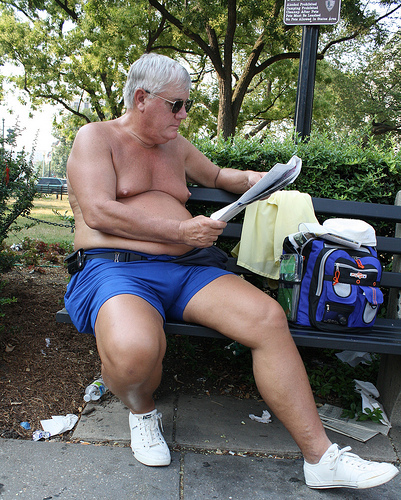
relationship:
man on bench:
[68, 49, 303, 474] [89, 182, 400, 346]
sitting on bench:
[64, 219, 231, 342] [89, 182, 400, 346]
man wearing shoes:
[68, 49, 303, 474] [126, 412, 173, 468]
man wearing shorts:
[68, 49, 303, 474] [67, 246, 233, 324]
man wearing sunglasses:
[68, 49, 303, 474] [164, 93, 194, 118]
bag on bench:
[280, 232, 383, 334] [89, 182, 400, 346]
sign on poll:
[282, 0, 342, 27] [298, 25, 316, 146]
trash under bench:
[321, 380, 389, 441] [89, 182, 400, 346]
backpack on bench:
[280, 232, 383, 334] [89, 182, 400, 346]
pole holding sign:
[298, 25, 316, 146] [282, 0, 342, 27]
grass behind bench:
[26, 197, 71, 227] [89, 182, 400, 346]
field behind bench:
[36, 185, 71, 222] [89, 182, 400, 346]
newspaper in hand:
[213, 153, 303, 224] [191, 214, 229, 247]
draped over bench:
[261, 188, 319, 272] [89, 182, 400, 346]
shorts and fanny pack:
[67, 246, 233, 324] [124, 247, 233, 267]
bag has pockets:
[280, 232, 383, 334] [326, 282, 381, 327]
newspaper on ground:
[323, 403, 393, 443] [319, 397, 401, 461]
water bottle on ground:
[81, 380, 106, 403] [81, 387, 117, 424]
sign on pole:
[282, 0, 342, 27] [298, 25, 316, 146]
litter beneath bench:
[321, 380, 389, 441] [89, 182, 400, 346]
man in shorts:
[68, 49, 303, 474] [67, 246, 233, 324]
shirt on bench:
[271, 188, 318, 237] [89, 182, 400, 346]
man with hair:
[68, 49, 303, 474] [126, 52, 190, 99]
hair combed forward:
[126, 52, 190, 99] [157, 58, 190, 85]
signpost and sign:
[298, 25, 316, 146] [282, 0, 342, 27]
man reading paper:
[68, 49, 303, 474] [213, 153, 303, 224]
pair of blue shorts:
[67, 246, 233, 324] [64, 219, 231, 342]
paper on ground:
[321, 380, 389, 441] [319, 397, 401, 461]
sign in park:
[282, 0, 342, 27] [232, 1, 398, 87]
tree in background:
[193, 2, 302, 131] [176, 1, 373, 119]